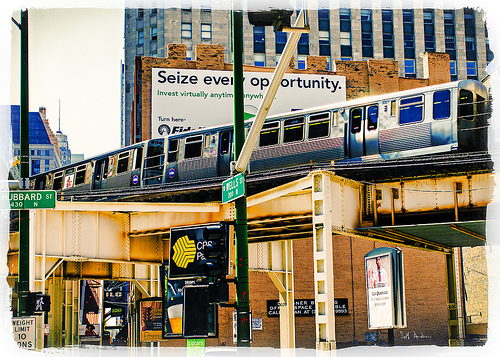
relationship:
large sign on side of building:
[153, 70, 347, 141] [134, 51, 447, 132]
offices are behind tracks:
[128, 11, 477, 57] [132, 155, 487, 210]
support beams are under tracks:
[308, 171, 336, 353] [132, 155, 487, 210]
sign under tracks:
[171, 226, 216, 269] [132, 155, 487, 210]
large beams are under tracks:
[364, 177, 496, 223] [132, 155, 487, 210]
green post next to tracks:
[237, 201, 245, 344] [132, 155, 487, 210]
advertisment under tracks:
[369, 251, 400, 332] [132, 155, 487, 210]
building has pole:
[50, 100, 75, 160] [54, 101, 63, 131]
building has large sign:
[134, 51, 447, 132] [153, 70, 347, 141]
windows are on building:
[334, 31, 361, 49] [134, 51, 447, 132]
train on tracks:
[81, 80, 499, 194] [132, 155, 487, 210]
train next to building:
[81, 80, 499, 194] [134, 51, 447, 132]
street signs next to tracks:
[8, 191, 61, 215] [132, 155, 487, 210]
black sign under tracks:
[267, 298, 350, 317] [132, 155, 487, 210]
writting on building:
[398, 326, 435, 343] [134, 51, 447, 132]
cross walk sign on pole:
[33, 291, 51, 313] [17, 220, 28, 314]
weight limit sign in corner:
[12, 320, 38, 347] [8, 304, 87, 352]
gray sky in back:
[35, 18, 102, 59] [46, 75, 132, 102]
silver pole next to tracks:
[230, 7, 317, 173] [132, 155, 487, 210]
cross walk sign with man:
[33, 291, 51, 313] [36, 297, 44, 311]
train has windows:
[81, 80, 499, 194] [187, 138, 199, 162]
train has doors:
[81, 80, 499, 194] [352, 106, 379, 149]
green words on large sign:
[155, 88, 234, 102] [153, 70, 347, 141]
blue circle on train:
[166, 169, 180, 179] [81, 80, 499, 194]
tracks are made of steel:
[132, 155, 487, 210] [361, 161, 428, 170]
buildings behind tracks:
[4, 99, 82, 161] [132, 155, 487, 210]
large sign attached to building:
[153, 70, 347, 141] [134, 51, 447, 132]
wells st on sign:
[226, 181, 244, 191] [221, 171, 246, 200]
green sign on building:
[187, 340, 212, 347] [134, 51, 447, 132]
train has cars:
[81, 80, 499, 194] [160, 81, 470, 151]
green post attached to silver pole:
[237, 201, 245, 344] [230, 7, 317, 173]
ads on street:
[104, 283, 131, 303] [81, 282, 99, 345]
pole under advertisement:
[54, 101, 63, 131] [369, 251, 400, 332]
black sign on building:
[267, 297, 352, 317] [134, 51, 447, 132]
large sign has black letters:
[153, 70, 347, 141] [159, 68, 232, 90]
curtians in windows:
[341, 34, 351, 45] [334, 31, 361, 49]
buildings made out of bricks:
[4, 99, 82, 161] [355, 76, 393, 92]